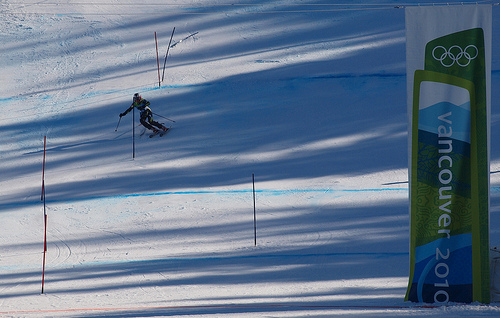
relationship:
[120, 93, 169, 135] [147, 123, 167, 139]
man on skiis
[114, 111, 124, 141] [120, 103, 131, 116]
rod in hand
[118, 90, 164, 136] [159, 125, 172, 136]
man on skies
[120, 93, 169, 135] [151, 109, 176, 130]
man holding pole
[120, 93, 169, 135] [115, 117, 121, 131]
man holding rod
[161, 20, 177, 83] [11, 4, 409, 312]
pole in snow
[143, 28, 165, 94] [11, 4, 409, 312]
pole in snow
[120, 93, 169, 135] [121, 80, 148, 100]
man wearing helmet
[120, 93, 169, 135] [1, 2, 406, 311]
man skiing down hill